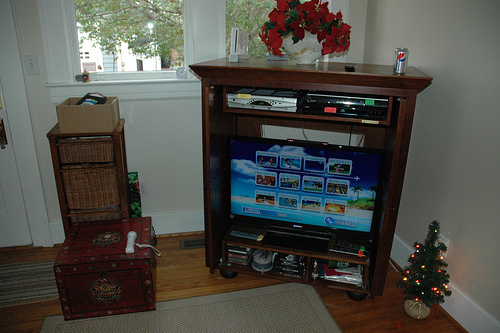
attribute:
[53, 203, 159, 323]
box — red, closed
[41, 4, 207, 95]
window — closed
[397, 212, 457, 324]
tree — christmasey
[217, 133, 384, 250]
tv — flat, black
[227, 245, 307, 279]
cds — stacked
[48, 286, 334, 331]
rug — tan, carpet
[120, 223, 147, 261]
remote — white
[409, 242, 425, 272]
lights — small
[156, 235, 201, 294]
floor — brown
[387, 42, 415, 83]
can — soda, pepsi, silver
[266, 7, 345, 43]
poinsettia — red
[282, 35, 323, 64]
vase — white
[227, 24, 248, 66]
wii — white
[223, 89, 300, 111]
box — grey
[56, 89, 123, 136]
cardboard — brown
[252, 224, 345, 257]
stand — black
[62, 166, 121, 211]
basket — wicker